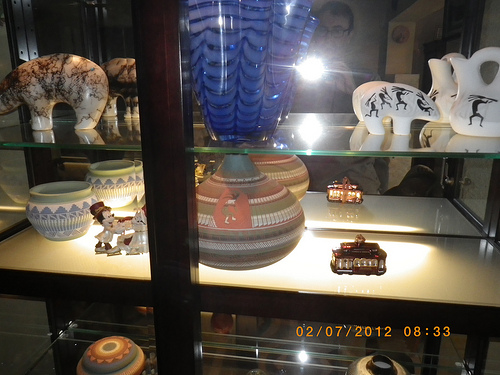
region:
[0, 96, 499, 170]
GLASS SHELF IN CABINET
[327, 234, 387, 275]
TOY TROLLEY ON SHELF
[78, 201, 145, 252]
DISNEY ACTION FIGURES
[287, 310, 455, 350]
DATE OF THE PHOTO TAKEN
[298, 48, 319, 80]
CAMERA FLASH REFLECTION IN MIRROR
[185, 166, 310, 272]
CERAMIC BOWL ON SHELF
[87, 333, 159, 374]
CERAMIC POT IN CABINET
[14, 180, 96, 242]
CERAMIC BOWL IN CABINET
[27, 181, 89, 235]
this is a vase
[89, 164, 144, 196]
this is a vase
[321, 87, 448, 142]
this is a sculpture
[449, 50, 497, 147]
this is a sculpture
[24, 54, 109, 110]
this is a sculpture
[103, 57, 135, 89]
this is a sculpture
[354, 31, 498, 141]
black and white pottery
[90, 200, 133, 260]
mickey mouse figurine in the cabinet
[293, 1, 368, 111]
reflection of person taking the photo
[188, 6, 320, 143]
blue vase in the cabinet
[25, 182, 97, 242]
blue, green, and white pottery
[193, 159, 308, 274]
striped round pottery in the cabinet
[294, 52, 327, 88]
glare of light on the mirror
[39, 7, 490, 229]
mirrored back wall of cabinet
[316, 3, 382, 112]
A reflection of a man on the glass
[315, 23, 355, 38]
The man is wearing eye glasses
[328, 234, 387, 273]
A miniature building is white, and brown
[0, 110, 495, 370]
The shelf's are made of glass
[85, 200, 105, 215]
Mickey mouse is wearing a hat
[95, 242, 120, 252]
Mickey mouse is wearing ice skates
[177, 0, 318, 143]
Glass art the color is clear, and blue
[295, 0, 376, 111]
The man is taking a picture of the items in case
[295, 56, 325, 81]
The flash on the camera is reflection on the glass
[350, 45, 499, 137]
The items on the top shelf have painted characters on them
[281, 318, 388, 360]
THIS IS A DATE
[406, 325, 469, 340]
THIS IS THE TIME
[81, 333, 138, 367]
THIS IS A VASE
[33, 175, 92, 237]
THIS IS A VASE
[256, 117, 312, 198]
THIS IS A VASE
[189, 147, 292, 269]
THIS IS A VASE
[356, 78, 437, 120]
THIS IS A SCULPTURE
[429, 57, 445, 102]
THIS IS A SCULPTURE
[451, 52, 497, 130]
THIS IS A SCULPTURE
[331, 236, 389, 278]
train car in the hutch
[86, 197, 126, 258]
statue of Mickey Mouse in the hutch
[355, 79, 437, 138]
white bear with indian pictures on it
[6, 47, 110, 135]
marble bear in the hutch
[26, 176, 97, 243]
pottery in the hutch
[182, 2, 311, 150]
blue glass vase in the hutch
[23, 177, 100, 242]
pottery is green, blue and white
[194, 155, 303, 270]
pottery is reddish, tan and white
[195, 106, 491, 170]
glass shelf in the hutch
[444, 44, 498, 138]
pottery with indian art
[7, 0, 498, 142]
Objects on the shelf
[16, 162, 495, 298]
Objects on the shelf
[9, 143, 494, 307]
Objects on the shelf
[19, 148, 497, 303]
Objects on the shelf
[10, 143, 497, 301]
Objects on the shelf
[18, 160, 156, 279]
Objects on the shelf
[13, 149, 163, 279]
Objects on the shelf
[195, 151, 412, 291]
Objects on the shelf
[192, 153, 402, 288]
Objects on the shelf